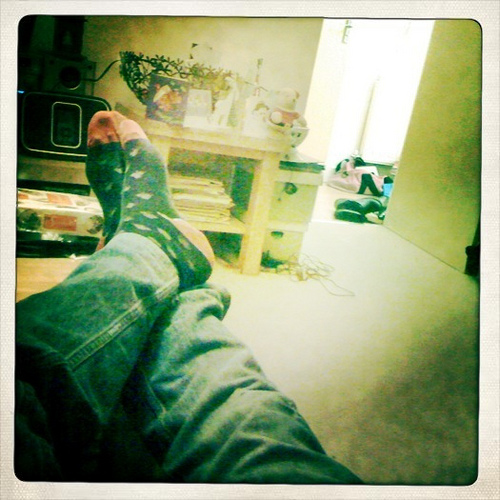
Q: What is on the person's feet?
A: Socks.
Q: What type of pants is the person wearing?
A: Jeans.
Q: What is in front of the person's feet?
A: A table.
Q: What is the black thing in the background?
A: An electronic device.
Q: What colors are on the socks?
A: Black and pink.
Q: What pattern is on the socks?
A: Polka dots.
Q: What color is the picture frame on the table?
A: Black.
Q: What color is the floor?
A: Cream.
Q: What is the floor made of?
A: Carpet.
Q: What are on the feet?
A: Socks.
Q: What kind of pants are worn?
A: Jeans.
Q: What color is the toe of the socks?
A: Pink.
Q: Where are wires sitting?
A: Near shelves on the floor.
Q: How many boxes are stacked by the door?
A: Two.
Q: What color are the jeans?
A: Blue.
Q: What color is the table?
A: Tan.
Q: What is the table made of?
A: Wood.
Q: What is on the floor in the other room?
A: Clothes.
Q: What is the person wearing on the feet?
A: Socks.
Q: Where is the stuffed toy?
A: On the table.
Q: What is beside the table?
A: Boxes.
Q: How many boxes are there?
A: Two.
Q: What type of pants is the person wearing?
A: Jeans.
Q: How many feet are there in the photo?
A: Two.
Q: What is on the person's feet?
A: Socks.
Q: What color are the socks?
A: Black and pink.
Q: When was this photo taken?
A: Daytime.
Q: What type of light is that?
A: Sunlight.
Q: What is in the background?
A: A table.